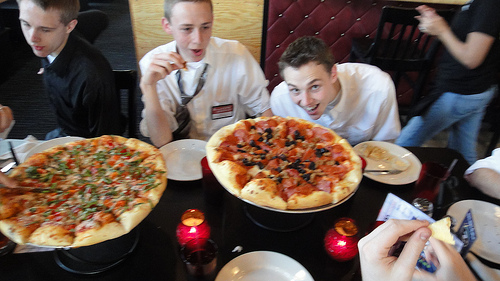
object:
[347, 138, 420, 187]
plate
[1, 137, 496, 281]
table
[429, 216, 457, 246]
food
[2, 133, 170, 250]
pizza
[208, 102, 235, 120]
name tag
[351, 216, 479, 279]
hands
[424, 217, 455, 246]
crust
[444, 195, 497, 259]
plate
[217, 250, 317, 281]
plate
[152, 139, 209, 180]
dinner plate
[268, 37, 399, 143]
man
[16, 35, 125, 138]
shirt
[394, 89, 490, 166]
jeans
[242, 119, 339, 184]
olive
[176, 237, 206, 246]
candleholder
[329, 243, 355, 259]
candleholder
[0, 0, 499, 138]
wall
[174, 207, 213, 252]
candle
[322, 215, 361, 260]
candle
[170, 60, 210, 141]
neck tie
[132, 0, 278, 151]
man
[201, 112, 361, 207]
pizza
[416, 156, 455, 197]
glass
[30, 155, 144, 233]
herbs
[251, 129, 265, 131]
topping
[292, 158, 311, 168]
topping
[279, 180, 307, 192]
topping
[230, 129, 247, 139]
topping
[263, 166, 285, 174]
topping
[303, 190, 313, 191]
topping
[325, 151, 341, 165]
topping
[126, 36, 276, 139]
shirt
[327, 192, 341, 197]
topping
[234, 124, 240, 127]
topping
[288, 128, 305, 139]
topping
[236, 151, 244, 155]
topping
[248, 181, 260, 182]
topping